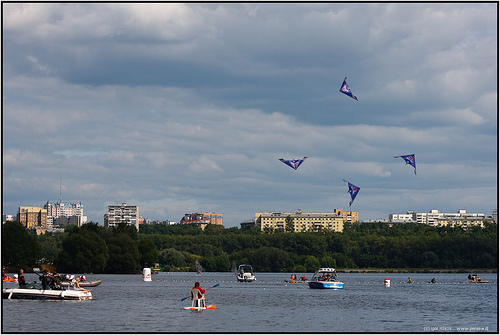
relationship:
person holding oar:
[190, 281, 207, 307] [178, 283, 220, 303]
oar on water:
[178, 283, 220, 303] [12, 263, 499, 330]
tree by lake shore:
[60, 223, 112, 275] [2, 218, 499, 270]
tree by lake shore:
[0, 220, 40, 271] [2, 218, 499, 270]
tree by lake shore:
[247, 245, 292, 270] [2, 218, 499, 270]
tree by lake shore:
[318, 255, 339, 270] [2, 218, 499, 270]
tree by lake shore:
[336, 255, 355, 269] [2, 218, 499, 270]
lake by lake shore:
[238, 269, 499, 334] [2, 218, 499, 270]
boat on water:
[308, 267, 344, 289] [301, 290, 418, 327]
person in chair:
[190, 281, 207, 307] [189, 289, 205, 308]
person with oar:
[190, 281, 207, 307] [176, 281, 221, 303]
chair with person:
[189, 289, 205, 308] [190, 281, 207, 307]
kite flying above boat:
[277, 156, 308, 170] [308, 267, 344, 289]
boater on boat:
[17, 269, 26, 289] [0, 266, 94, 301]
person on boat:
[73, 277, 91, 292] [0, 266, 94, 301]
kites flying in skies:
[392, 151, 416, 171] [0, 0, 500, 223]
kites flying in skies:
[338, 71, 358, 102] [0, 0, 500, 223]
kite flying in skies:
[342, 178, 361, 207] [0, 0, 500, 223]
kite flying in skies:
[277, 156, 308, 170] [0, 0, 500, 223]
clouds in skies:
[6, 5, 494, 215] [0, 0, 500, 223]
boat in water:
[308, 267, 344, 289] [29, 269, 459, 328]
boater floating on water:
[317, 272, 335, 279] [3, 270, 495, 330]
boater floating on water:
[13, 265, 25, 285] [3, 270, 495, 330]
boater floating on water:
[78, 272, 89, 282] [3, 270, 495, 330]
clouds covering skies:
[0, 0, 500, 229] [0, 0, 500, 223]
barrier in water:
[384, 277, 391, 287] [274, 298, 439, 323]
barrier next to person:
[384, 277, 391, 287] [431, 277, 437, 283]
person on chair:
[185, 278, 214, 303] [191, 295, 214, 312]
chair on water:
[191, 295, 214, 312] [15, 268, 484, 321]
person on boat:
[73, 277, 91, 292] [0, 287, 93, 301]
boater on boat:
[17, 269, 26, 289] [0, 287, 93, 301]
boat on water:
[236, 264, 256, 282] [148, 282, 303, 319]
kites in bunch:
[338, 76, 359, 101] [268, 68, 429, 218]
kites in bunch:
[392, 154, 417, 176] [268, 68, 429, 218]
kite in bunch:
[277, 154, 314, 176] [268, 68, 429, 218]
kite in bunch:
[337, 170, 362, 214] [268, 68, 429, 218]